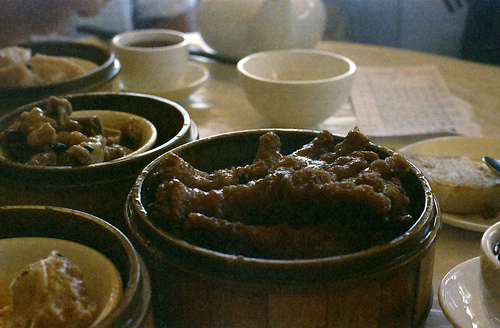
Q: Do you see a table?
A: Yes, there is a table.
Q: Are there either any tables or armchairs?
A: Yes, there is a table.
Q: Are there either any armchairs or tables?
A: Yes, there is a table.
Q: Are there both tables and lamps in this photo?
A: No, there is a table but no lamps.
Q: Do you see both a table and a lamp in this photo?
A: No, there is a table but no lamps.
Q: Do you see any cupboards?
A: No, there are no cupboards.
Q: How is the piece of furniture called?
A: The piece of furniture is a table.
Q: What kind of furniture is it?
A: The piece of furniture is a table.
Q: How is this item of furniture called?
A: This is a table.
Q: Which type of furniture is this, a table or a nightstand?
A: This is a table.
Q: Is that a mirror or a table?
A: That is a table.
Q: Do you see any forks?
A: No, there are no forks.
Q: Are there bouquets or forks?
A: No, there are no forks or bouquets.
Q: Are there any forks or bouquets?
A: No, there are no forks or bouquets.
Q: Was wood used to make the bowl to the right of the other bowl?
A: Yes, the bowl is made of wood.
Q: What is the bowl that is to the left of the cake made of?
A: The bowl is made of wood.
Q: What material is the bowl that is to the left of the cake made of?
A: The bowl is made of wood.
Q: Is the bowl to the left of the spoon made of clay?
A: No, the bowl is made of wood.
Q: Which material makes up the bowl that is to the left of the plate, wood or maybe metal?
A: The bowl is made of wood.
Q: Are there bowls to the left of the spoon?
A: Yes, there is a bowl to the left of the spoon.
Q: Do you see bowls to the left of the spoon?
A: Yes, there is a bowl to the left of the spoon.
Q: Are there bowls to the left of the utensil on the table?
A: Yes, there is a bowl to the left of the spoon.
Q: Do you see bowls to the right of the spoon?
A: No, the bowl is to the left of the spoon.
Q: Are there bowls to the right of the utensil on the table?
A: No, the bowl is to the left of the spoon.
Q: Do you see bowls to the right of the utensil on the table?
A: No, the bowl is to the left of the spoon.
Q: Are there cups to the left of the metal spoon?
A: No, there is a bowl to the left of the spoon.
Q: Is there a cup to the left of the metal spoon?
A: No, there is a bowl to the left of the spoon.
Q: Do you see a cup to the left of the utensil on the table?
A: No, there is a bowl to the left of the spoon.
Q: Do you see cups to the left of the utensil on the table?
A: No, there is a bowl to the left of the spoon.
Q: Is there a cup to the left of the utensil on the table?
A: No, there is a bowl to the left of the spoon.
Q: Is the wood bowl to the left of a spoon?
A: Yes, the bowl is to the left of a spoon.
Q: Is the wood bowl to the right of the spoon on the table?
A: No, the bowl is to the left of the spoon.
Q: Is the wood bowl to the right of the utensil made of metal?
A: No, the bowl is to the left of the spoon.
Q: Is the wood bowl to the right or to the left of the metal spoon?
A: The bowl is to the left of the spoon.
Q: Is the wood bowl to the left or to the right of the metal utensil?
A: The bowl is to the left of the spoon.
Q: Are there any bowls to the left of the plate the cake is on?
A: Yes, there is a bowl to the left of the plate.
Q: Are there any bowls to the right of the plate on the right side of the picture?
A: No, the bowl is to the left of the plate.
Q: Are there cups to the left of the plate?
A: No, there is a bowl to the left of the plate.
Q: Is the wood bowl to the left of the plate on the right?
A: Yes, the bowl is to the left of the plate.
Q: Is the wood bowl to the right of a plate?
A: No, the bowl is to the left of a plate.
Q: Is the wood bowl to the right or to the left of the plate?
A: The bowl is to the left of the plate.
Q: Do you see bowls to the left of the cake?
A: Yes, there is a bowl to the left of the cake.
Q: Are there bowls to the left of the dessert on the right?
A: Yes, there is a bowl to the left of the cake.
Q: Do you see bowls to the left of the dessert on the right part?
A: Yes, there is a bowl to the left of the cake.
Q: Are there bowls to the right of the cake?
A: No, the bowl is to the left of the cake.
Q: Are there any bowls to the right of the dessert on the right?
A: No, the bowl is to the left of the cake.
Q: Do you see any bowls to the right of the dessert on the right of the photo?
A: No, the bowl is to the left of the cake.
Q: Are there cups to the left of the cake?
A: No, there is a bowl to the left of the cake.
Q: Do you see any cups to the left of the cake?
A: No, there is a bowl to the left of the cake.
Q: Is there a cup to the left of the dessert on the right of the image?
A: No, there is a bowl to the left of the cake.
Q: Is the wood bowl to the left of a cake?
A: Yes, the bowl is to the left of a cake.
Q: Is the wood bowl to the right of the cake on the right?
A: No, the bowl is to the left of the cake.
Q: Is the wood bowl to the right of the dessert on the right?
A: No, the bowl is to the left of the cake.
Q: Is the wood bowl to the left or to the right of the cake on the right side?
A: The bowl is to the left of the cake.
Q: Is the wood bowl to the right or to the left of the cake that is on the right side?
A: The bowl is to the left of the cake.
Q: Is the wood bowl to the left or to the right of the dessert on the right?
A: The bowl is to the left of the cake.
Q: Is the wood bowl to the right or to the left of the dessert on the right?
A: The bowl is to the left of the cake.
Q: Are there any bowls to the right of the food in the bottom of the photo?
A: Yes, there is a bowl to the right of the food.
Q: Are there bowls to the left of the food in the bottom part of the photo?
A: No, the bowl is to the right of the food.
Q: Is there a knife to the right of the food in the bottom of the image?
A: No, there is a bowl to the right of the food.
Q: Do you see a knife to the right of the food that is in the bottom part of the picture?
A: No, there is a bowl to the right of the food.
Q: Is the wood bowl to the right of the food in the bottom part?
A: Yes, the bowl is to the right of the food.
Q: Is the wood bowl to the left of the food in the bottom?
A: No, the bowl is to the right of the food.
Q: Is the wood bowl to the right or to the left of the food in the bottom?
A: The bowl is to the right of the food.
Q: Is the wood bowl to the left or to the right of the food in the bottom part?
A: The bowl is to the right of the food.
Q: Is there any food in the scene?
A: Yes, there is food.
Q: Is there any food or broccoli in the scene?
A: Yes, there is food.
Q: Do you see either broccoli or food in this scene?
A: Yes, there is food.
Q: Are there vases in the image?
A: No, there are no vases.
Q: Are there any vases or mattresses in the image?
A: No, there are no vases or mattresses.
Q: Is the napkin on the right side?
A: Yes, the napkin is on the right of the image.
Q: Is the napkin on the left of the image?
A: No, the napkin is on the right of the image.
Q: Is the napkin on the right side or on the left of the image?
A: The napkin is on the right of the image.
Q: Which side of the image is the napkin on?
A: The napkin is on the right of the image.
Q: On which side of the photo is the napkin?
A: The napkin is on the right of the image.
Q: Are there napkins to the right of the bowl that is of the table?
A: Yes, there is a napkin to the right of the bowl.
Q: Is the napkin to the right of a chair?
A: No, the napkin is to the right of the bowl.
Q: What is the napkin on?
A: The napkin is on the table.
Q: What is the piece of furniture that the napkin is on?
A: The piece of furniture is a table.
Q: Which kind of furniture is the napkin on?
A: The napkin is on the table.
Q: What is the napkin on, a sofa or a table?
A: The napkin is on a table.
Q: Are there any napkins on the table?
A: Yes, there is a napkin on the table.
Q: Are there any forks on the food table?
A: No, there is a napkin on the table.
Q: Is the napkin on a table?
A: Yes, the napkin is on a table.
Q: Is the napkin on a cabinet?
A: No, the napkin is on a table.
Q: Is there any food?
A: Yes, there is food.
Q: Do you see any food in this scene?
A: Yes, there is food.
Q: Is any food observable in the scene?
A: Yes, there is food.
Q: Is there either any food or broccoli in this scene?
A: Yes, there is food.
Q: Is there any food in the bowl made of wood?
A: Yes, there is food in the bowl.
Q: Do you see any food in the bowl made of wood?
A: Yes, there is food in the bowl.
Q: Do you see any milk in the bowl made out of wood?
A: No, there is food in the bowl.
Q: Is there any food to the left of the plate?
A: Yes, there is food to the left of the plate.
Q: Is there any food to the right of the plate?
A: No, the food is to the left of the plate.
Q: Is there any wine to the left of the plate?
A: No, there is food to the left of the plate.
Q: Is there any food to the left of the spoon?
A: Yes, there is food to the left of the spoon.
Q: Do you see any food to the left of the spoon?
A: Yes, there is food to the left of the spoon.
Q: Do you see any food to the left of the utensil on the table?
A: Yes, there is food to the left of the spoon.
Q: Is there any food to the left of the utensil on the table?
A: Yes, there is food to the left of the spoon.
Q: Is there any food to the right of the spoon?
A: No, the food is to the left of the spoon.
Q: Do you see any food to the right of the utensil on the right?
A: No, the food is to the left of the spoon.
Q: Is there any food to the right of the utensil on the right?
A: No, the food is to the left of the spoon.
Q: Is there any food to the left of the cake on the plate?
A: Yes, there is food to the left of the cake.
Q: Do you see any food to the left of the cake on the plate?
A: Yes, there is food to the left of the cake.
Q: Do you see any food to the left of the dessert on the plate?
A: Yes, there is food to the left of the cake.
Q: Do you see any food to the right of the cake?
A: No, the food is to the left of the cake.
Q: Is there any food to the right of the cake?
A: No, the food is to the left of the cake.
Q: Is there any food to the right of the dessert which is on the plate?
A: No, the food is to the left of the cake.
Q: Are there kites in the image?
A: No, there are no kites.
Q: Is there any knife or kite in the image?
A: No, there are no kites or knives.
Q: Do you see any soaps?
A: No, there are no soaps.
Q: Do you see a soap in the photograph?
A: No, there are no soaps.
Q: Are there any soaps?
A: No, there are no soaps.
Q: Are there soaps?
A: No, there are no soaps.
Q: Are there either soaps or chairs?
A: No, there are no soaps or chairs.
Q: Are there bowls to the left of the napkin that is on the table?
A: Yes, there is a bowl to the left of the napkin.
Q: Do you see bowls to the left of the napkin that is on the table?
A: Yes, there is a bowl to the left of the napkin.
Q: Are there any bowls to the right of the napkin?
A: No, the bowl is to the left of the napkin.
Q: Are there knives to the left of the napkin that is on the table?
A: No, there is a bowl to the left of the napkin.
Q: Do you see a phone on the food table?
A: No, there is a bowl on the table.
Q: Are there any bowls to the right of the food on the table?
A: No, the bowl is to the left of the food.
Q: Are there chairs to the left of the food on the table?
A: No, there is a bowl to the left of the food.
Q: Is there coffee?
A: Yes, there is coffee.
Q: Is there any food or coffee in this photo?
A: Yes, there is coffee.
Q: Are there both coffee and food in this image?
A: Yes, there are both coffee and food.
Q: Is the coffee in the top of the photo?
A: Yes, the coffee is in the top of the image.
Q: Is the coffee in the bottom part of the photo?
A: No, the coffee is in the top of the image.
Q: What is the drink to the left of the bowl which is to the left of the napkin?
A: The drink is coffee.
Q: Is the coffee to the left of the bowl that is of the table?
A: Yes, the coffee is to the left of the bowl.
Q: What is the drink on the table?
A: The drink is coffee.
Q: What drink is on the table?
A: The drink is coffee.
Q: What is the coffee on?
A: The coffee is on the table.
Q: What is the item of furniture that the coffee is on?
A: The piece of furniture is a table.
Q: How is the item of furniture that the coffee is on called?
A: The piece of furniture is a table.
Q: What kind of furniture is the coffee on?
A: The coffee is on the table.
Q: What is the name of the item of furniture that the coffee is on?
A: The piece of furniture is a table.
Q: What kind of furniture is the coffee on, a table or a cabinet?
A: The coffee is on a table.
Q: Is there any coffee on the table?
A: Yes, there is coffee on the table.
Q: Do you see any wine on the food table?
A: No, there is coffee on the table.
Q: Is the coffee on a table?
A: Yes, the coffee is on a table.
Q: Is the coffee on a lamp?
A: No, the coffee is on a table.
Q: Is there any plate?
A: Yes, there is a plate.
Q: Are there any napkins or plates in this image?
A: Yes, there is a plate.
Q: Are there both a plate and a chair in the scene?
A: No, there is a plate but no chairs.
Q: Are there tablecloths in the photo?
A: No, there are no tablecloths.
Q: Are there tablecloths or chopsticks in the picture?
A: No, there are no tablecloths or chopsticks.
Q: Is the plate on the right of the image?
A: Yes, the plate is on the right of the image.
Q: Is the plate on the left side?
A: No, the plate is on the right of the image.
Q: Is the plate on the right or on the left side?
A: The plate is on the right of the image.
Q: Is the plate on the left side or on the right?
A: The plate is on the right of the image.